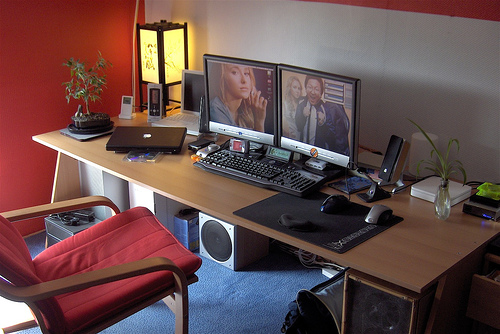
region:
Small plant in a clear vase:
[408, 119, 469, 222]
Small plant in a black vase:
[55, 51, 117, 136]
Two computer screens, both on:
[191, 48, 359, 171]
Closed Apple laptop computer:
[103, 122, 189, 154]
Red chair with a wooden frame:
[0, 170, 220, 332]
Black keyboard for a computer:
[192, 140, 329, 197]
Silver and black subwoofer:
[191, 209, 251, 274]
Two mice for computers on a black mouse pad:
[320, 192, 395, 230]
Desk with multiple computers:
[27, 15, 496, 289]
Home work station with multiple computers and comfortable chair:
[2, 1, 496, 331]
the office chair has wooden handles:
[7, 175, 191, 315]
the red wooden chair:
[34, 217, 213, 322]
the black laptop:
[107, 106, 205, 158]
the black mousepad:
[252, 188, 422, 283]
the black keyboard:
[192, 135, 389, 233]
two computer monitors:
[193, 45, 468, 165]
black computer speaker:
[365, 125, 432, 210]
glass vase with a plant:
[430, 138, 459, 253]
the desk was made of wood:
[358, 243, 418, 255]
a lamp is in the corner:
[126, 20, 251, 114]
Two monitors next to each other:
[194, 49, 371, 174]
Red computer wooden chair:
[0, 190, 205, 330]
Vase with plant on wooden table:
[405, 115, 470, 216]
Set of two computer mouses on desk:
[314, 190, 399, 226]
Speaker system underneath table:
[194, 203, 276, 268]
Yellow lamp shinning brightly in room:
[134, 19, 191, 86]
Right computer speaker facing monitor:
[375, 128, 411, 183]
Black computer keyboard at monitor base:
[190, 146, 336, 195]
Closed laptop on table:
[99, 118, 192, 153]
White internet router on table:
[406, 172, 473, 205]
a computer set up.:
[186, 50, 366, 198]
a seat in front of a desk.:
[0, 188, 205, 330]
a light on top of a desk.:
[126, 15, 198, 95]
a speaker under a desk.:
[191, 212, 241, 271]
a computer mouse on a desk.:
[356, 188, 397, 234]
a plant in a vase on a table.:
[46, 43, 116, 153]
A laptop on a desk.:
[95, 111, 194, 160]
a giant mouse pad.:
[232, 170, 406, 258]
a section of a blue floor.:
[223, 291, 252, 310]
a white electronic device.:
[399, 163, 481, 213]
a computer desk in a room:
[30, 38, 488, 323]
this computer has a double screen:
[179, 50, 366, 179]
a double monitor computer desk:
[189, 47, 363, 214]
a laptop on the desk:
[90, 115, 195, 168]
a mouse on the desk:
[352, 199, 409, 236]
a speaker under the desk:
[179, 209, 264, 269]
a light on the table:
[123, 16, 191, 121]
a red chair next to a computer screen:
[11, 192, 207, 329]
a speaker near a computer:
[369, 132, 409, 199]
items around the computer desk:
[268, 265, 424, 332]